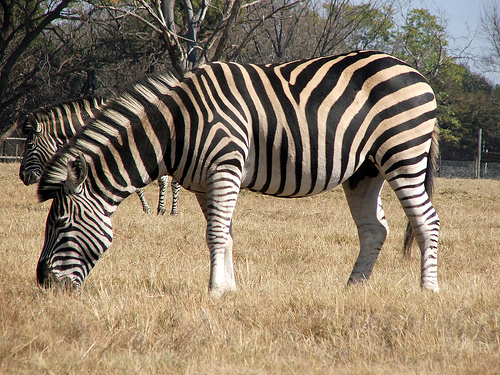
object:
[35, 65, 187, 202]
mane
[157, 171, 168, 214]
legs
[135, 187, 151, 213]
legs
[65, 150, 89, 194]
ear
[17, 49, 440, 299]
two zebras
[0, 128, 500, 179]
fence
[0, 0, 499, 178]
background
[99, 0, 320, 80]
tree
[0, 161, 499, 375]
grass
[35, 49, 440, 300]
zebra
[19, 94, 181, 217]
animal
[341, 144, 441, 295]
back legs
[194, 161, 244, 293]
legs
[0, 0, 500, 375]
pasture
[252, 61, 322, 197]
stripe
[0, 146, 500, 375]
field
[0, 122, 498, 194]
distance